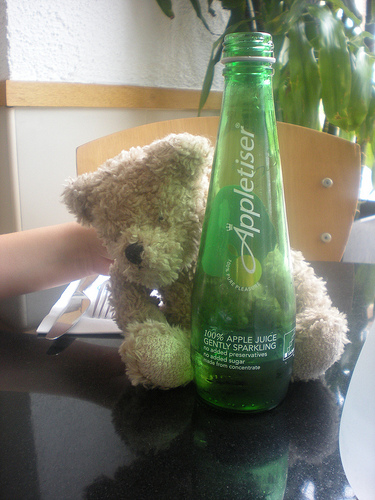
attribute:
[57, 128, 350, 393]
teddy bear — brown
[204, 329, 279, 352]
words — apple juice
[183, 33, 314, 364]
bottle — green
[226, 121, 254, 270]
word — white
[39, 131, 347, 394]
teddybear — white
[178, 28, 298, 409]
bottle — big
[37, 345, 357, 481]
surface — brown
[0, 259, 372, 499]
counter — black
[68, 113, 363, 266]
seat — brown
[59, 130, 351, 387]
stuffed bear — brown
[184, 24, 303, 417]
bottle — big, green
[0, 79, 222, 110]
strip — wooden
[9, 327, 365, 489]
surface — reflective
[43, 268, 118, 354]
knife — silvery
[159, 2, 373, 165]
plant — in background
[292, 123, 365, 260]
seat — wooden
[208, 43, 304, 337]
bottle — big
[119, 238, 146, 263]
nose — black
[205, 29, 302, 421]
juice — big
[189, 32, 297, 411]
bottle — apple juice, blue, big, green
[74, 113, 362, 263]
chair — wooden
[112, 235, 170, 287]
mouth — white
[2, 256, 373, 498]
surface — marbled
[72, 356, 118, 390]
table — reflective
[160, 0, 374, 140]
plants — green yellow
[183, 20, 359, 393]
bottle — green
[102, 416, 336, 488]
table — black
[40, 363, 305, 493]
table — metallic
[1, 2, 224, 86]
wall — white